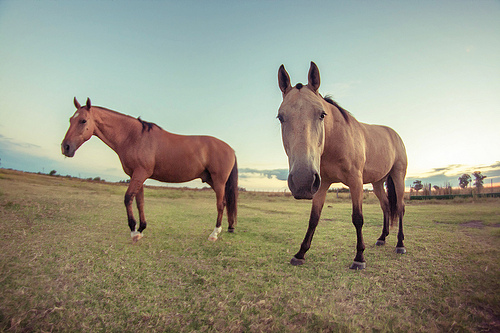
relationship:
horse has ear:
[276, 60, 411, 275] [305, 58, 321, 90]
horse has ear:
[276, 60, 411, 275] [271, 62, 293, 94]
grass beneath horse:
[145, 240, 287, 285] [276, 60, 411, 275]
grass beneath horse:
[145, 240, 287, 285] [60, 95, 240, 242]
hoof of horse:
[207, 234, 219, 241] [60, 95, 240, 242]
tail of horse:
[228, 145, 255, 229] [50, 87, 265, 263]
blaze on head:
[68, 100, 85, 123] [57, 105, 100, 163]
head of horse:
[57, 105, 100, 163] [61, 100, 252, 233]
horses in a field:
[55, 52, 421, 274] [0, 167, 499, 331]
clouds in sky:
[3, 131, 498, 191] [2, 1, 499, 192]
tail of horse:
[225, 156, 239, 229] [60, 95, 240, 242]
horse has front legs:
[276, 60, 411, 275] [289, 203, 367, 273]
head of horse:
[274, 60, 330, 200] [276, 60, 411, 275]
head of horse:
[61, 97, 94, 158] [60, 95, 240, 242]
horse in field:
[276, 60, 411, 275] [32, 263, 339, 323]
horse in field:
[60, 95, 240, 242] [32, 263, 339, 323]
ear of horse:
[275, 62, 292, 92] [276, 60, 411, 275]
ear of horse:
[305, 60, 322, 89] [276, 60, 411, 275]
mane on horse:
[317, 90, 352, 130] [252, 52, 439, 276]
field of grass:
[0, 167, 499, 331] [68, 250, 299, 330]